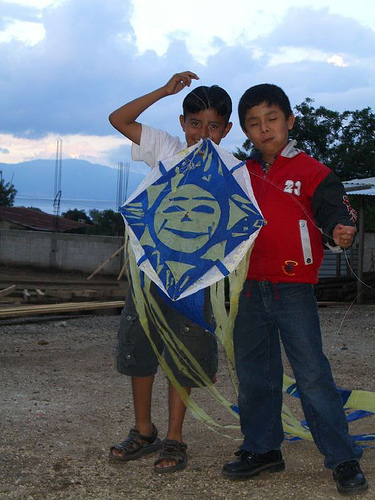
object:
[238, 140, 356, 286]
jacket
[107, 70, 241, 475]
boy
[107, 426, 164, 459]
sandal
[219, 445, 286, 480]
shoe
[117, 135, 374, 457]
kite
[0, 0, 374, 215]
sky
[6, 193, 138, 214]
line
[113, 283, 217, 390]
shorts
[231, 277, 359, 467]
jeans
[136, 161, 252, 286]
sun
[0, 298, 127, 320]
plank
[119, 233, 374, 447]
tail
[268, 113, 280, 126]
eye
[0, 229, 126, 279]
wall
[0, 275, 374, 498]
ground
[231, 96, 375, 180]
tree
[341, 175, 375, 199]
roof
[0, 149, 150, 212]
mountain